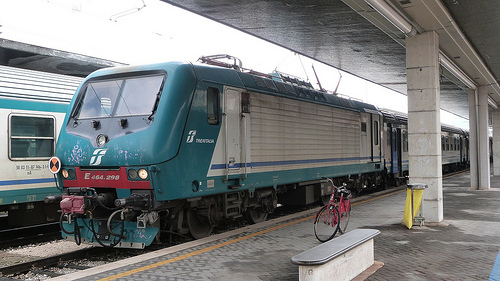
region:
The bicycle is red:
[307, 163, 370, 237]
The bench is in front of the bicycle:
[287, 217, 402, 279]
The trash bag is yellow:
[399, 178, 427, 233]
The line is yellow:
[89, 219, 277, 277]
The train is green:
[42, 55, 404, 246]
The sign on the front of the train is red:
[53, 160, 181, 210]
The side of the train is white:
[196, 76, 387, 176]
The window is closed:
[5, 106, 70, 177]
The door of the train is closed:
[362, 108, 401, 173]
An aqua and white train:
[50, 54, 493, 249]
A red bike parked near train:
[312, 176, 353, 243]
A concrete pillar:
[402, 29, 444, 226]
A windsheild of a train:
[74, 71, 168, 119]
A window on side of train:
[7, 109, 57, 161]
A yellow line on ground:
[100, 164, 472, 280]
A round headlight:
[137, 166, 149, 180]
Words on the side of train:
[195, 136, 215, 144]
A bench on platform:
[291, 227, 382, 279]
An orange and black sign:
[46, 155, 61, 174]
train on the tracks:
[34, 37, 498, 259]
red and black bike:
[309, 175, 366, 242]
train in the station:
[43, 55, 493, 250]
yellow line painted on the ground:
[95, 178, 421, 279]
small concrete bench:
[280, 220, 395, 277]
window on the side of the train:
[5, 106, 60, 161]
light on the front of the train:
[135, 165, 145, 180]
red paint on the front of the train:
[57, 165, 142, 190]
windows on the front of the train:
[70, 72, 165, 122]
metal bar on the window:
[10, 130, 57, 142]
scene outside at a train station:
[3, 3, 498, 277]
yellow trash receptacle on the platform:
[403, 182, 426, 230]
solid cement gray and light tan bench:
[289, 226, 383, 278]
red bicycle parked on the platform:
[312, 178, 354, 243]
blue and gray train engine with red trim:
[46, 51, 386, 243]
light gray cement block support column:
[401, 27, 446, 226]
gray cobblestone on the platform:
[38, 168, 495, 274]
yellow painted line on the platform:
[97, 186, 404, 274]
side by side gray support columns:
[464, 82, 490, 190]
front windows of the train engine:
[71, 69, 163, 119]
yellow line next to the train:
[125, 179, 427, 278]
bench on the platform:
[286, 218, 389, 278]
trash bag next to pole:
[395, 168, 455, 246]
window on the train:
[4, 103, 64, 159]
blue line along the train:
[201, 144, 389, 182]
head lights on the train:
[57, 160, 166, 200]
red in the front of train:
[56, 165, 161, 194]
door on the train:
[363, 112, 396, 174]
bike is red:
[309, 164, 373, 246]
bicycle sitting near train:
[310, 176, 353, 241]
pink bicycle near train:
[312, 175, 353, 245]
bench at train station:
[289, 226, 381, 279]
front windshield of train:
[71, 71, 166, 119]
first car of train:
[46, 59, 381, 252]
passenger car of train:
[380, 106, 463, 184]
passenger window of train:
[401, 129, 406, 153]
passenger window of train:
[440, 134, 445, 150]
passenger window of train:
[8, 113, 55, 163]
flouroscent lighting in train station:
[438, 49, 478, 95]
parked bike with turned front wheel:
[313, 177, 352, 241]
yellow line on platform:
[59, 186, 407, 278]